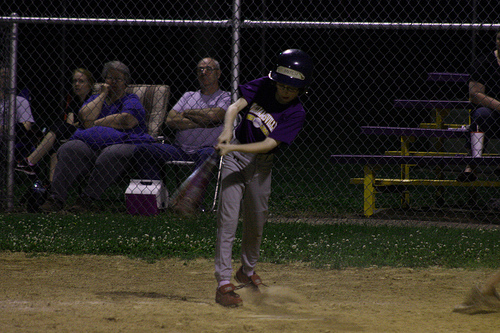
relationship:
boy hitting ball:
[238, 78, 286, 151] [22, 177, 51, 196]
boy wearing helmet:
[238, 78, 286, 151] [270, 50, 294, 66]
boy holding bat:
[238, 78, 286, 151] [199, 151, 223, 206]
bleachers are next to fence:
[360, 116, 426, 161] [328, 22, 374, 62]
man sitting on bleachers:
[465, 60, 495, 129] [360, 116, 426, 161]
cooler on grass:
[136, 176, 155, 213] [123, 226, 168, 244]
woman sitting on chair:
[85, 68, 151, 142] [156, 85, 172, 101]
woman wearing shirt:
[85, 68, 151, 142] [228, 96, 274, 119]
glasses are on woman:
[105, 75, 120, 82] [85, 68, 151, 142]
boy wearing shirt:
[238, 78, 286, 151] [228, 96, 274, 119]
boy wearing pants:
[238, 78, 286, 151] [226, 220, 261, 259]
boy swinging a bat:
[238, 78, 286, 151] [199, 151, 223, 206]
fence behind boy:
[328, 22, 374, 62] [238, 78, 286, 151]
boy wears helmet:
[238, 78, 286, 151] [270, 50, 294, 66]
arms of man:
[166, 102, 214, 129] [465, 60, 495, 129]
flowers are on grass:
[296, 231, 327, 249] [123, 226, 168, 244]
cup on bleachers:
[464, 134, 484, 156] [360, 116, 426, 161]